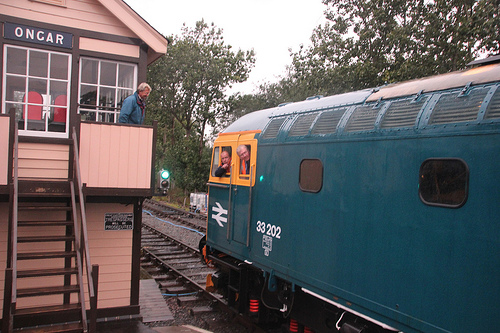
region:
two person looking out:
[210, 137, 281, 189]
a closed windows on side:
[282, 150, 349, 200]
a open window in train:
[402, 152, 458, 213]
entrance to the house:
[13, 130, 116, 313]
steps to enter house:
[23, 201, 80, 318]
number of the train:
[246, 222, 307, 246]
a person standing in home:
[121, 70, 160, 140]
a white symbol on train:
[183, 197, 245, 231]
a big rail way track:
[136, 219, 276, 327]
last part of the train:
[191, 101, 498, 331]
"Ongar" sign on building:
[12, 21, 72, 47]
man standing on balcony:
[108, 81, 150, 123]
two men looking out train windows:
[212, 140, 254, 184]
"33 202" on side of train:
[253, 217, 284, 241]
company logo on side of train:
[207, 197, 228, 227]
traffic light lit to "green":
[157, 161, 172, 193]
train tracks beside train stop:
[137, 206, 233, 326]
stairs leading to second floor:
[7, 110, 100, 330]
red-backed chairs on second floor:
[17, 88, 69, 128]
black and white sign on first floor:
[100, 210, 137, 231]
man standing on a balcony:
[87, 67, 165, 132]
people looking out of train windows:
[185, 110, 260, 184]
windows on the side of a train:
[231, 132, 477, 259]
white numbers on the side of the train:
[227, 211, 294, 258]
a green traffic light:
[139, 150, 185, 197]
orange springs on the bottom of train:
[208, 275, 270, 321]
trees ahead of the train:
[145, 27, 262, 195]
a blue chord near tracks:
[145, 190, 202, 241]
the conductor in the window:
[192, 135, 265, 185]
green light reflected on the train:
[235, 157, 275, 212]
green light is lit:
[155, 163, 174, 194]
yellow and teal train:
[203, 93, 485, 328]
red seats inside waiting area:
[17, 87, 72, 130]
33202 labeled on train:
[253, 217, 285, 239]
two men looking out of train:
[212, 135, 256, 183]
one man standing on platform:
[116, 78, 153, 125]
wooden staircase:
[5, 109, 98, 325]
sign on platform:
[7, 20, 75, 50]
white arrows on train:
[204, 196, 230, 235]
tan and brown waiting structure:
[2, 2, 167, 320]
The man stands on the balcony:
[113, 77, 168, 144]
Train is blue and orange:
[208, 103, 419, 330]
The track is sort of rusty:
[155, 210, 194, 315]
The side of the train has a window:
[417, 150, 477, 215]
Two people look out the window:
[205, 134, 267, 185]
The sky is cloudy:
[230, 11, 315, 89]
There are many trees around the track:
[302, 5, 493, 82]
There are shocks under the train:
[243, 280, 258, 332]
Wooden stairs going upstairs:
[9, 144, 83, 331]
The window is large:
[10, 40, 95, 171]